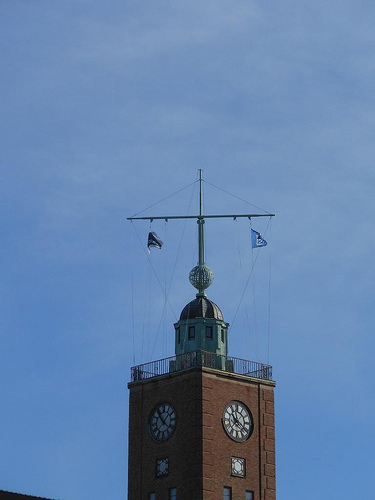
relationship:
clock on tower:
[218, 393, 259, 444] [113, 163, 288, 500]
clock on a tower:
[218, 393, 259, 444] [113, 163, 288, 500]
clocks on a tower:
[145, 399, 180, 444] [113, 163, 288, 500]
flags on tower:
[249, 227, 270, 251] [113, 163, 288, 500]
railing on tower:
[126, 349, 275, 394] [113, 163, 288, 500]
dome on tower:
[169, 296, 235, 369] [113, 163, 288, 500]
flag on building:
[141, 226, 174, 254] [113, 163, 288, 500]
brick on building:
[204, 423, 216, 431] [113, 163, 288, 500]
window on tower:
[218, 482, 239, 499] [113, 163, 288, 500]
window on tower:
[166, 484, 181, 497] [113, 163, 288, 500]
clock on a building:
[218, 393, 259, 444] [113, 163, 288, 500]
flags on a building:
[130, 217, 275, 252] [113, 163, 288, 500]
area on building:
[126, 349, 275, 394] [119, 169, 280, 498]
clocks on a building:
[142, 394, 258, 444] [113, 163, 288, 500]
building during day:
[119, 169, 280, 498] [104, 27, 279, 126]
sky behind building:
[75, 63, 308, 373] [113, 163, 288, 500]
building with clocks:
[113, 163, 288, 500] [142, 394, 258, 444]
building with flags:
[113, 163, 288, 500] [130, 217, 275, 252]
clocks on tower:
[142, 394, 258, 444] [113, 163, 288, 500]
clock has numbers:
[218, 393, 259, 444] [224, 402, 252, 440]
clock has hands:
[218, 393, 259, 444] [224, 402, 252, 440]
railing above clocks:
[126, 349, 275, 394] [142, 394, 258, 444]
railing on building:
[126, 349, 275, 394] [113, 163, 288, 500]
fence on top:
[126, 349, 275, 394] [126, 325, 284, 389]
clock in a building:
[218, 393, 259, 444] [113, 163, 288, 500]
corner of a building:
[268, 380, 282, 499] [113, 163, 288, 500]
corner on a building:
[195, 363, 210, 497] [119, 169, 280, 498]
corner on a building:
[121, 364, 138, 498] [119, 169, 280, 498]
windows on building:
[215, 482, 257, 500] [119, 169, 280, 498]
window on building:
[166, 484, 178, 499] [119, 169, 280, 498]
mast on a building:
[124, 167, 273, 264] [119, 169, 280, 498]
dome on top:
[169, 296, 235, 369] [126, 325, 284, 389]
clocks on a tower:
[142, 394, 258, 444] [113, 163, 288, 500]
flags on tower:
[130, 217, 275, 252] [113, 163, 288, 500]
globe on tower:
[184, 260, 217, 292] [113, 163, 288, 500]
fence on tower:
[126, 349, 275, 394] [113, 163, 288, 500]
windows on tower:
[141, 484, 262, 499] [113, 163, 288, 500]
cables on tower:
[142, 253, 176, 358] [113, 163, 288, 500]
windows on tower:
[215, 482, 257, 500] [113, 163, 288, 500]